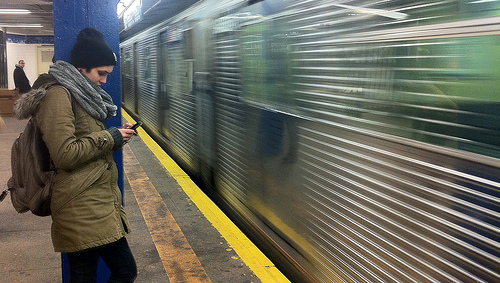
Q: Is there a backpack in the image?
A: Yes, there is a backpack.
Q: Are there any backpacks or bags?
A: Yes, there is a backpack.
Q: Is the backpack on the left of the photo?
A: Yes, the backpack is on the left of the image.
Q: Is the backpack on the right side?
A: No, the backpack is on the left of the image.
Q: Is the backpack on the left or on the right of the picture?
A: The backpack is on the left of the image.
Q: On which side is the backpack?
A: The backpack is on the left of the image.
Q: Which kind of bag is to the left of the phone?
A: The bag is a backpack.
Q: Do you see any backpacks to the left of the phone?
A: Yes, there is a backpack to the left of the phone.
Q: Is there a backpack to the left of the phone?
A: Yes, there is a backpack to the left of the phone.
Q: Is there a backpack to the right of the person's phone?
A: No, the backpack is to the left of the telephone.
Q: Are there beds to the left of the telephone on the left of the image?
A: No, there is a backpack to the left of the telephone.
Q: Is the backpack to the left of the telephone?
A: Yes, the backpack is to the left of the telephone.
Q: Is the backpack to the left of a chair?
A: No, the backpack is to the left of the telephone.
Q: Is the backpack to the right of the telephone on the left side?
A: No, the backpack is to the left of the telephone.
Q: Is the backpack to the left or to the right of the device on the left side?
A: The backpack is to the left of the telephone.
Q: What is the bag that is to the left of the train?
A: The bag is a backpack.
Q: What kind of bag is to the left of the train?
A: The bag is a backpack.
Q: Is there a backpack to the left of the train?
A: Yes, there is a backpack to the left of the train.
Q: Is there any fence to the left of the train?
A: No, there is a backpack to the left of the train.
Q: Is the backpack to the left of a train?
A: Yes, the backpack is to the left of a train.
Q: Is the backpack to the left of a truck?
A: No, the backpack is to the left of a train.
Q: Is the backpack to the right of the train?
A: No, the backpack is to the left of the train.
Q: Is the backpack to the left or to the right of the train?
A: The backpack is to the left of the train.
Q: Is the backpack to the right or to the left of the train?
A: The backpack is to the left of the train.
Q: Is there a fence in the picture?
A: No, there are no fences.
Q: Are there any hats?
A: Yes, there is a hat.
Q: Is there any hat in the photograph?
A: Yes, there is a hat.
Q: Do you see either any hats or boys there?
A: Yes, there is a hat.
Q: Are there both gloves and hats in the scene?
A: No, there is a hat but no gloves.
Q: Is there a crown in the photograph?
A: No, there are no crowns.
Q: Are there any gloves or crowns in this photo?
A: No, there are no crowns or gloves.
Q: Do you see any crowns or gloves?
A: No, there are no crowns or gloves.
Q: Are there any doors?
A: Yes, there is a door.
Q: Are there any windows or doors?
A: Yes, there is a door.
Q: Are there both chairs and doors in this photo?
A: No, there is a door but no chairs.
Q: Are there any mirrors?
A: No, there are no mirrors.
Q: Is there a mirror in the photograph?
A: No, there are no mirrors.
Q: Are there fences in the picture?
A: No, there are no fences.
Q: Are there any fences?
A: No, there are no fences.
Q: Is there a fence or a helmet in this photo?
A: No, there are no fences or helmets.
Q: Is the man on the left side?
A: Yes, the man is on the left of the image.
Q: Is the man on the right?
A: No, the man is on the left of the image.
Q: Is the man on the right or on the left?
A: The man is on the left of the image.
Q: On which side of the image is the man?
A: The man is on the left of the image.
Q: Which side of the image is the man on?
A: The man is on the left of the image.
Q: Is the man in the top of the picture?
A: Yes, the man is in the top of the image.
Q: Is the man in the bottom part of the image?
A: No, the man is in the top of the image.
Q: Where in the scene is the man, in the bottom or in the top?
A: The man is in the top of the image.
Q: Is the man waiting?
A: Yes, the man is waiting.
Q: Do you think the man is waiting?
A: Yes, the man is waiting.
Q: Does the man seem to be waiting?
A: Yes, the man is waiting.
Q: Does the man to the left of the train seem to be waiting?
A: Yes, the man is waiting.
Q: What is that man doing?
A: The man is waiting.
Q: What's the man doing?
A: The man is waiting.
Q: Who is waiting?
A: The man is waiting.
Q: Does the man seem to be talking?
A: No, the man is waiting.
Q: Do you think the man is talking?
A: No, the man is waiting.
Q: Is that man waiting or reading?
A: The man is waiting.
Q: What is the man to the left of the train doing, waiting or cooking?
A: The man is waiting.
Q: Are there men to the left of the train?
A: Yes, there is a man to the left of the train.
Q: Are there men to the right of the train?
A: No, the man is to the left of the train.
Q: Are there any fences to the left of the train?
A: No, there is a man to the left of the train.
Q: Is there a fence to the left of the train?
A: No, there is a man to the left of the train.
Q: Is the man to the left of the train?
A: Yes, the man is to the left of the train.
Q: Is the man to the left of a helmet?
A: No, the man is to the left of the train.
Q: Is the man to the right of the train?
A: No, the man is to the left of the train.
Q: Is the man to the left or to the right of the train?
A: The man is to the left of the train.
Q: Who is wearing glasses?
A: The man is wearing glasses.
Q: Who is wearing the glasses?
A: The man is wearing glasses.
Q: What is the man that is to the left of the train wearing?
A: The man is wearing glasses.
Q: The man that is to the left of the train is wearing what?
A: The man is wearing glasses.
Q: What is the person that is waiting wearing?
A: The man is wearing glasses.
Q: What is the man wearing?
A: The man is wearing glasses.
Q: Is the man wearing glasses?
A: Yes, the man is wearing glasses.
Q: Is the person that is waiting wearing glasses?
A: Yes, the man is wearing glasses.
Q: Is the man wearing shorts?
A: No, the man is wearing glasses.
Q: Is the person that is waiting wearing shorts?
A: No, the man is wearing glasses.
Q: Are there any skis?
A: No, there are no skis.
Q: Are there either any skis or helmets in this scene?
A: No, there are no skis or helmets.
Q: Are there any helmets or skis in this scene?
A: No, there are no skis or helmets.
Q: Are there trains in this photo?
A: Yes, there is a train.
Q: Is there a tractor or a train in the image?
A: Yes, there is a train.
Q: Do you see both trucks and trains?
A: No, there is a train but no trucks.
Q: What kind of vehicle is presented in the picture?
A: The vehicle is a train.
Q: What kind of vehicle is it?
A: The vehicle is a train.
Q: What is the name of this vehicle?
A: This is a train.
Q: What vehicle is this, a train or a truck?
A: This is a train.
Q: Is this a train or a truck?
A: This is a train.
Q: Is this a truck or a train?
A: This is a train.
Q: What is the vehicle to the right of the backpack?
A: The vehicle is a train.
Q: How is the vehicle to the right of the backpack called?
A: The vehicle is a train.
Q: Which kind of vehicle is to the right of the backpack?
A: The vehicle is a train.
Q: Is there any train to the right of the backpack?
A: Yes, there is a train to the right of the backpack.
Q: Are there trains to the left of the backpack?
A: No, the train is to the right of the backpack.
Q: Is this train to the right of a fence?
A: No, the train is to the right of the backpack.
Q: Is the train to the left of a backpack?
A: No, the train is to the right of a backpack.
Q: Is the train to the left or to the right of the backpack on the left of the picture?
A: The train is to the right of the backpack.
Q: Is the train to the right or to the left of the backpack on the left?
A: The train is to the right of the backpack.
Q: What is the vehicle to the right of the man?
A: The vehicle is a train.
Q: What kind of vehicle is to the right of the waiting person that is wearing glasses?
A: The vehicle is a train.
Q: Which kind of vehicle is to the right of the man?
A: The vehicle is a train.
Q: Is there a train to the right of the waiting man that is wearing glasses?
A: Yes, there is a train to the right of the man.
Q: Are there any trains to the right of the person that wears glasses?
A: Yes, there is a train to the right of the man.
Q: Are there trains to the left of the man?
A: No, the train is to the right of the man.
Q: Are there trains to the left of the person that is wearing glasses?
A: No, the train is to the right of the man.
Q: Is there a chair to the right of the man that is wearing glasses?
A: No, there is a train to the right of the man.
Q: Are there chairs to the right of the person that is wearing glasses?
A: No, there is a train to the right of the man.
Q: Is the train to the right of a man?
A: Yes, the train is to the right of a man.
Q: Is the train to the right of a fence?
A: No, the train is to the right of a man.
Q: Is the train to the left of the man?
A: No, the train is to the right of the man.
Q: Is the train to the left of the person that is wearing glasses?
A: No, the train is to the right of the man.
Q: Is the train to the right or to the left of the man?
A: The train is to the right of the man.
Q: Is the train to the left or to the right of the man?
A: The train is to the right of the man.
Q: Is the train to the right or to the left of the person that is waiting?
A: The train is to the right of the man.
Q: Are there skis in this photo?
A: No, there are no skis.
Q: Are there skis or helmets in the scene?
A: No, there are no skis or helmets.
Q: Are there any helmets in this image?
A: No, there are no helmets.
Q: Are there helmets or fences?
A: No, there are no helmets or fences.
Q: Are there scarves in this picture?
A: Yes, there is a scarf.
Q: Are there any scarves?
A: Yes, there is a scarf.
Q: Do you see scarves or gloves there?
A: Yes, there is a scarf.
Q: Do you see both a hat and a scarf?
A: Yes, there are both a scarf and a hat.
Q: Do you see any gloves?
A: No, there are no gloves.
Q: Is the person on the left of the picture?
A: Yes, the person is on the left of the image.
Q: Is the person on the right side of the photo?
A: No, the person is on the left of the image.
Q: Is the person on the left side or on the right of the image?
A: The person is on the left of the image.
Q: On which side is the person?
A: The person is on the left of the image.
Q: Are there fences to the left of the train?
A: No, there is a person to the left of the train.